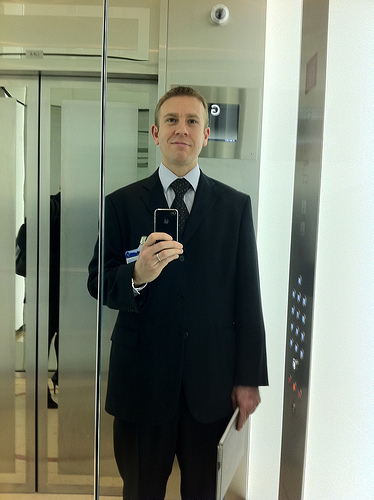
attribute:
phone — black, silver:
[153, 207, 179, 240]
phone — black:
[152, 207, 178, 242]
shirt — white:
[132, 158, 214, 209]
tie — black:
[167, 184, 186, 208]